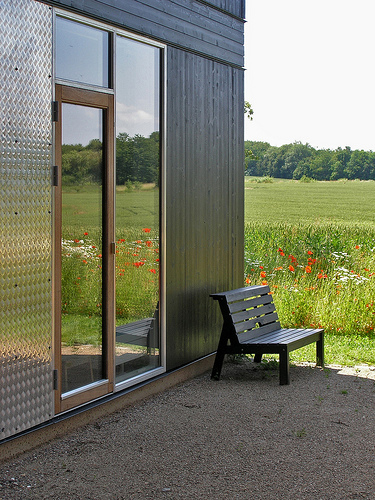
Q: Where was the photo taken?
A: It was taken at the patio.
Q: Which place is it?
A: It is a patio.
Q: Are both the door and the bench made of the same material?
A: No, the door is made of glass and the bench is made of wood.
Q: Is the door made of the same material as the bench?
A: No, the door is made of glass and the bench is made of wood.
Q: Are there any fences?
A: No, there are no fences.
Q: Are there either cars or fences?
A: No, there are no fences or cars.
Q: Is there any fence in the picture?
A: No, there are no fences.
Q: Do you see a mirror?
A: Yes, there is a mirror.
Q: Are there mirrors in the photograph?
A: Yes, there is a mirror.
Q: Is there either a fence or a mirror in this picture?
A: Yes, there is a mirror.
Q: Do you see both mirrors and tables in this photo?
A: No, there is a mirror but no tables.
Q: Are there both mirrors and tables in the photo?
A: No, there is a mirror but no tables.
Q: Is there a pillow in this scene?
A: No, there are no pillows.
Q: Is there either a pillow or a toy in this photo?
A: No, there are no pillows or toys.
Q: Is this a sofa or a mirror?
A: This is a mirror.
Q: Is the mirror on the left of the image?
A: Yes, the mirror is on the left of the image.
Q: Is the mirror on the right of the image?
A: No, the mirror is on the left of the image.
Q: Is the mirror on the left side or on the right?
A: The mirror is on the left of the image.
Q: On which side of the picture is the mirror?
A: The mirror is on the left of the image.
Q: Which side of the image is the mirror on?
A: The mirror is on the left of the image.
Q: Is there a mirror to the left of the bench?
A: Yes, there is a mirror to the left of the bench.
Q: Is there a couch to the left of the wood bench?
A: No, there is a mirror to the left of the bench.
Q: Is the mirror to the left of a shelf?
A: No, the mirror is to the left of the bench.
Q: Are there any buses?
A: No, there are no buses.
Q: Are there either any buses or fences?
A: No, there are no buses or fences.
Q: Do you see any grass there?
A: Yes, there is grass.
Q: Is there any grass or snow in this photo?
A: Yes, there is grass.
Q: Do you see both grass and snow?
A: No, there is grass but no snow.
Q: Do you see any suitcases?
A: No, there are no suitcases.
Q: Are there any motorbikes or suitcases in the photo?
A: No, there are no suitcases or motorbikes.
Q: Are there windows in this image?
A: Yes, there is a window.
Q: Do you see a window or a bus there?
A: Yes, there is a window.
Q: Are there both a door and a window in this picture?
A: Yes, there are both a window and a door.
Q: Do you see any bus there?
A: No, there are no buses.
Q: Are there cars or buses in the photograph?
A: No, there are no buses or cars.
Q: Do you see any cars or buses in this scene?
A: No, there are no buses or cars.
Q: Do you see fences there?
A: No, there are no fences.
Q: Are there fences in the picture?
A: No, there are no fences.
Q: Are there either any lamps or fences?
A: No, there are no fences or lamps.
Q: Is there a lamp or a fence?
A: No, there are no fences or lamps.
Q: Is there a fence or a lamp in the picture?
A: No, there are no fences or lamps.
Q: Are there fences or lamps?
A: No, there are no fences or lamps.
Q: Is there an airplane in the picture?
A: No, there are no airplanes.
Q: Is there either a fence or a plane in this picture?
A: No, there are no airplanes or fences.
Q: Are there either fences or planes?
A: No, there are no planes or fences.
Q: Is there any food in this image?
A: No, there is no food.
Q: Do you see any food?
A: No, there is no food.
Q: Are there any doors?
A: Yes, there is a door.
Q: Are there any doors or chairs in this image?
A: Yes, there is a door.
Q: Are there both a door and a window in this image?
A: Yes, there are both a door and a window.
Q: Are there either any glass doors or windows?
A: Yes, there is a glass door.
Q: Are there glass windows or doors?
A: Yes, there is a glass door.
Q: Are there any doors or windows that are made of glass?
A: Yes, the door is made of glass.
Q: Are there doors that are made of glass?
A: Yes, there is a door that is made of glass.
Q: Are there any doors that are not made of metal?
A: Yes, there is a door that is made of glass.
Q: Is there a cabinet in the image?
A: No, there are no cabinets.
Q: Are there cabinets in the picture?
A: No, there are no cabinets.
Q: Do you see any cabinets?
A: No, there are no cabinets.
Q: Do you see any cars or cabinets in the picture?
A: No, there are no cabinets or cars.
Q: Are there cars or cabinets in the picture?
A: No, there are no cabinets or cars.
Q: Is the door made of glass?
A: Yes, the door is made of glass.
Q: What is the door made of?
A: The door is made of glass.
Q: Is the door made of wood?
A: No, the door is made of glass.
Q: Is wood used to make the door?
A: No, the door is made of glass.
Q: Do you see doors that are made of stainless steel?
A: No, there is a door but it is made of glass.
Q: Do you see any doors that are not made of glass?
A: No, there is a door but it is made of glass.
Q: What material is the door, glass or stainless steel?
A: The door is made of glass.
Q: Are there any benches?
A: Yes, there is a bench.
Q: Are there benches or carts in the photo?
A: Yes, there is a bench.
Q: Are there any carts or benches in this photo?
A: Yes, there is a bench.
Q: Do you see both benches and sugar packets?
A: No, there is a bench but no sugar packets.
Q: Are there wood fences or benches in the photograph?
A: Yes, there is a wood bench.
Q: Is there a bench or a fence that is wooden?
A: Yes, the bench is wooden.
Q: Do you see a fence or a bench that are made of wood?
A: Yes, the bench is made of wood.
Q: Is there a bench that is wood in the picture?
A: Yes, there is a wood bench.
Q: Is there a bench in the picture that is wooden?
A: Yes, there is a bench that is wooden.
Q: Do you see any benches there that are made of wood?
A: Yes, there is a bench that is made of wood.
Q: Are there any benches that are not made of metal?
A: Yes, there is a bench that is made of wood.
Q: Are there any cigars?
A: No, there are no cigars.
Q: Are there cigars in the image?
A: No, there are no cigars.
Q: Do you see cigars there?
A: No, there are no cigars.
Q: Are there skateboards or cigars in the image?
A: No, there are no cigars or skateboards.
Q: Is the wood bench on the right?
A: Yes, the bench is on the right of the image.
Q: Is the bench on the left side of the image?
A: No, the bench is on the right of the image.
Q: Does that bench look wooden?
A: Yes, the bench is wooden.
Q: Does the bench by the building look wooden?
A: Yes, the bench is wooden.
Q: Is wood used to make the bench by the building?
A: Yes, the bench is made of wood.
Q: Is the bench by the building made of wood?
A: Yes, the bench is made of wood.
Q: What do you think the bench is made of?
A: The bench is made of wood.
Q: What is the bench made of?
A: The bench is made of wood.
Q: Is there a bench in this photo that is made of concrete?
A: No, there is a bench but it is made of wood.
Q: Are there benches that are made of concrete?
A: No, there is a bench but it is made of wood.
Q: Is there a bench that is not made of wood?
A: No, there is a bench but it is made of wood.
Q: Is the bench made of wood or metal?
A: The bench is made of wood.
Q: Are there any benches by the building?
A: Yes, there is a bench by the building.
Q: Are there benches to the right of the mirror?
A: Yes, there is a bench to the right of the mirror.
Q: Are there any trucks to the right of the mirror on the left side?
A: No, there is a bench to the right of the mirror.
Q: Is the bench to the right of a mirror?
A: Yes, the bench is to the right of a mirror.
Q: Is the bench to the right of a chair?
A: No, the bench is to the right of a mirror.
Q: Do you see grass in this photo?
A: Yes, there is grass.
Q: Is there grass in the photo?
A: Yes, there is grass.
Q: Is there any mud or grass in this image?
A: Yes, there is grass.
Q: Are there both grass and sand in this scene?
A: No, there is grass but no sand.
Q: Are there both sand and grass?
A: No, there is grass but no sand.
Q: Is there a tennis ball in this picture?
A: No, there are no tennis balls.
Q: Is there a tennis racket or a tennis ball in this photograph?
A: No, there are no tennis balls or rackets.